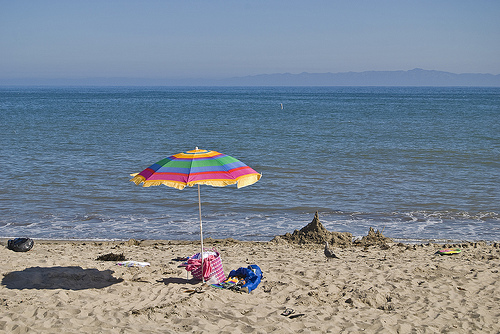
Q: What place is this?
A: It is a beach.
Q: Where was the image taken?
A: It was taken at the beach.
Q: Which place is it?
A: It is a beach.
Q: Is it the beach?
A: Yes, it is the beach.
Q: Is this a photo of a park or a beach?
A: It is showing a beach.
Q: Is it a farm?
A: No, it is a beach.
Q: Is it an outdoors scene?
A: Yes, it is outdoors.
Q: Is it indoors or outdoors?
A: It is outdoors.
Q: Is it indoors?
A: No, it is outdoors.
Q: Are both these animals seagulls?
A: Yes, all the animals are seagulls.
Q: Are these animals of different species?
A: No, all the animals are seagulls.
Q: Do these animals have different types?
A: No, all the animals are seagulls.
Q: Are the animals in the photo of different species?
A: No, all the animals are seagulls.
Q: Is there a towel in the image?
A: Yes, there is a towel.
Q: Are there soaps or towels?
A: Yes, there is a towel.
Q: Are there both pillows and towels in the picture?
A: No, there is a towel but no pillows.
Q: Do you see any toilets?
A: No, there are no toilets.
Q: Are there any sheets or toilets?
A: No, there are no toilets or sheets.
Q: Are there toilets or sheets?
A: No, there are no toilets or sheets.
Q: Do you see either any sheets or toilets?
A: No, there are no toilets or sheets.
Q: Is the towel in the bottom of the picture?
A: Yes, the towel is in the bottom of the image.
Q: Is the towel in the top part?
A: No, the towel is in the bottom of the image.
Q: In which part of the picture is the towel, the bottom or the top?
A: The towel is in the bottom of the image.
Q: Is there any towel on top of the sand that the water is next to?
A: Yes, there is a towel on top of the sand.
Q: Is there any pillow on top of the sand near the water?
A: No, there is a towel on top of the sand.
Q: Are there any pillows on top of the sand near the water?
A: No, there is a towel on top of the sand.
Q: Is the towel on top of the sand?
A: Yes, the towel is on top of the sand.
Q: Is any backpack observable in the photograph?
A: Yes, there is a backpack.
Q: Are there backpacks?
A: Yes, there is a backpack.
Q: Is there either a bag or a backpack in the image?
A: Yes, there is a backpack.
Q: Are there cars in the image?
A: No, there are no cars.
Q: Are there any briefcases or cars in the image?
A: No, there are no cars or briefcases.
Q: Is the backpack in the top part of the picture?
A: No, the backpack is in the bottom of the image.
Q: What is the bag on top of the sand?
A: The bag is a backpack.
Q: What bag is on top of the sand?
A: The bag is a backpack.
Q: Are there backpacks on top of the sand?
A: Yes, there is a backpack on top of the sand.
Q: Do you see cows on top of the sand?
A: No, there is a backpack on top of the sand.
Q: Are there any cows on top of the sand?
A: No, there is a backpack on top of the sand.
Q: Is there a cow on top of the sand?
A: No, there is a backpack on top of the sand.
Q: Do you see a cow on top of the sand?
A: No, there is a backpack on top of the sand.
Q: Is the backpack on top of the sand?
A: Yes, the backpack is on top of the sand.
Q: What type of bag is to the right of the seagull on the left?
A: The bag is a backpack.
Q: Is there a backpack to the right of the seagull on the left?
A: Yes, there is a backpack to the right of the seagull.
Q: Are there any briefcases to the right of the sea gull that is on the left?
A: No, there is a backpack to the right of the seagull.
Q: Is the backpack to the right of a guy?
A: No, the backpack is to the right of a seagull.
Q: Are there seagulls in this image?
A: Yes, there is a seagull.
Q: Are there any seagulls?
A: Yes, there is a seagull.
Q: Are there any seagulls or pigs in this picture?
A: Yes, there is a seagull.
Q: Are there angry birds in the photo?
A: No, there are no angry birds.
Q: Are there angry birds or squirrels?
A: No, there are no angry birds or squirrels.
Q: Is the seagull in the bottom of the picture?
A: Yes, the seagull is in the bottom of the image.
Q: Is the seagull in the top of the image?
A: No, the seagull is in the bottom of the image.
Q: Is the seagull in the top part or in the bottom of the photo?
A: The seagull is in the bottom of the image.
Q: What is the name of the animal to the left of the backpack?
A: The animal is a seagull.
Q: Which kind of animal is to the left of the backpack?
A: The animal is a seagull.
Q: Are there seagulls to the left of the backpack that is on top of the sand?
A: Yes, there is a seagull to the left of the backpack.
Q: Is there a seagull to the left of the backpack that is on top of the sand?
A: Yes, there is a seagull to the left of the backpack.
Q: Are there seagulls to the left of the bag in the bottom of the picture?
A: Yes, there is a seagull to the left of the backpack.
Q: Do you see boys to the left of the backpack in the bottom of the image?
A: No, there is a seagull to the left of the backpack.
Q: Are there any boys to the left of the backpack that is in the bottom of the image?
A: No, there is a seagull to the left of the backpack.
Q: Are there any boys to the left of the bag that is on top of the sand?
A: No, there is a seagull to the left of the backpack.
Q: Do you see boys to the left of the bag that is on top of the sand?
A: No, there is a seagull to the left of the backpack.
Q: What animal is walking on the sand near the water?
A: The sea gull is walking on the sand.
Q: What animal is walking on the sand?
A: The sea gull is walking on the sand.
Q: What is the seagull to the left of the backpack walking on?
A: The sea gull is walking on the sand.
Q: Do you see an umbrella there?
A: Yes, there is an umbrella.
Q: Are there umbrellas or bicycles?
A: Yes, there is an umbrella.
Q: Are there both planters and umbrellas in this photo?
A: No, there is an umbrella but no planters.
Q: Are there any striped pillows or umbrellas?
A: Yes, there is a striped umbrella.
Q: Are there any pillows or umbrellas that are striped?
A: Yes, the umbrella is striped.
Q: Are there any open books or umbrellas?
A: Yes, there is an open umbrella.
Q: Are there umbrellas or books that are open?
A: Yes, the umbrella is open.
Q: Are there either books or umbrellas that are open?
A: Yes, the umbrella is open.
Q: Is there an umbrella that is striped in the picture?
A: Yes, there is a striped umbrella.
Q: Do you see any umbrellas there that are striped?
A: Yes, there is an umbrella that is striped.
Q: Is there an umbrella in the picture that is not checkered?
A: Yes, there is a striped umbrella.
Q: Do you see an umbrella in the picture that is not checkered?
A: Yes, there is a striped umbrella.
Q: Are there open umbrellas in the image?
A: Yes, there is an open umbrella.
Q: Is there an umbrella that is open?
A: Yes, there is an umbrella that is open.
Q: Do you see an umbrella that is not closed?
A: Yes, there is a open umbrella.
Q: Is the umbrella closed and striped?
A: No, the umbrella is striped but open.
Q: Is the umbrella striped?
A: Yes, the umbrella is striped.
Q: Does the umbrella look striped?
A: Yes, the umbrella is striped.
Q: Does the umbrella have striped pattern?
A: Yes, the umbrella is striped.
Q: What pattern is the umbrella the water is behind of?
A: The umbrella is striped.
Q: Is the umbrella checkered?
A: No, the umbrella is striped.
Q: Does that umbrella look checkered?
A: No, the umbrella is striped.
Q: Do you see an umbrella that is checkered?
A: No, there is an umbrella but it is striped.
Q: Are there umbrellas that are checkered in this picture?
A: No, there is an umbrella but it is striped.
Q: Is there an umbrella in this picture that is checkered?
A: No, there is an umbrella but it is striped.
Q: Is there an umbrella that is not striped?
A: No, there is an umbrella but it is striped.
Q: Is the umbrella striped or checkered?
A: The umbrella is striped.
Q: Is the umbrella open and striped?
A: Yes, the umbrella is open and striped.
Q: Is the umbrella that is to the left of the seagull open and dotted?
A: No, the umbrella is open but striped.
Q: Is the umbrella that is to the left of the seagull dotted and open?
A: No, the umbrella is open but striped.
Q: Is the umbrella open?
A: Yes, the umbrella is open.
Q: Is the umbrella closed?
A: No, the umbrella is open.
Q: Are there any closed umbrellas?
A: No, there is an umbrella but it is open.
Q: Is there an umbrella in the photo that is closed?
A: No, there is an umbrella but it is open.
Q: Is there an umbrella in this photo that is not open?
A: No, there is an umbrella but it is open.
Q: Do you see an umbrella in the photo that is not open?
A: No, there is an umbrella but it is open.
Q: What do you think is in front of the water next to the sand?
A: The umbrella is in front of the water.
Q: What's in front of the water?
A: The umbrella is in front of the water.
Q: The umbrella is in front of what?
A: The umbrella is in front of the water.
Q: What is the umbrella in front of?
A: The umbrella is in front of the water.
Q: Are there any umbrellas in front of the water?
A: Yes, there is an umbrella in front of the water.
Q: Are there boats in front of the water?
A: No, there is an umbrella in front of the water.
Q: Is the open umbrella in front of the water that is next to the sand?
A: Yes, the umbrella is in front of the water.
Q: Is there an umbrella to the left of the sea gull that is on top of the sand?
A: Yes, there is an umbrella to the left of the sea gull.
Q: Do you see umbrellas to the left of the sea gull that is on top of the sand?
A: Yes, there is an umbrella to the left of the sea gull.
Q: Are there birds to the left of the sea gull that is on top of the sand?
A: No, there is an umbrella to the left of the seagull.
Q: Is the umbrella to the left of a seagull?
A: Yes, the umbrella is to the left of a seagull.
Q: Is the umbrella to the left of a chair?
A: No, the umbrella is to the left of a seagull.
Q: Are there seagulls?
A: Yes, there is a seagull.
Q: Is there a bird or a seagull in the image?
A: Yes, there is a seagull.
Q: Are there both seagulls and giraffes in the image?
A: No, there is a seagull but no giraffes.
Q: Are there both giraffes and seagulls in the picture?
A: No, there is a seagull but no giraffes.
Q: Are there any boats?
A: No, there are no boats.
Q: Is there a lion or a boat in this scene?
A: No, there are no boats or lions.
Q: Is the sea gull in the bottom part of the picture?
A: Yes, the sea gull is in the bottom of the image.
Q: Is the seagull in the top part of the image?
A: No, the seagull is in the bottom of the image.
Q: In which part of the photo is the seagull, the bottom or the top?
A: The seagull is in the bottom of the image.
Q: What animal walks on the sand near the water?
A: The sea gull walks on the sand.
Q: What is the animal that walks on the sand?
A: The animal is a seagull.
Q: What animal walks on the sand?
A: The animal is a seagull.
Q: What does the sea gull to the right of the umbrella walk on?
A: The seagull walks on the sand.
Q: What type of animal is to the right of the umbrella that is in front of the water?
A: The animal is a seagull.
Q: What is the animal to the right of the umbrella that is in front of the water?
A: The animal is a seagull.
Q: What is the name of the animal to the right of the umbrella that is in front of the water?
A: The animal is a seagull.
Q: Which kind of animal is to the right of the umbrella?
A: The animal is a seagull.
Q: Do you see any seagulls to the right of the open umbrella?
A: Yes, there is a seagull to the right of the umbrella.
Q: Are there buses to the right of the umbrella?
A: No, there is a seagull to the right of the umbrella.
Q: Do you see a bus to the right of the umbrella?
A: No, there is a seagull to the right of the umbrella.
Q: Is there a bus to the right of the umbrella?
A: No, there is a seagull to the right of the umbrella.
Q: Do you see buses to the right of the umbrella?
A: No, there is a seagull to the right of the umbrella.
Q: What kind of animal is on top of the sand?
A: The animal is a seagull.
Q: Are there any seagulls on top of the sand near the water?
A: Yes, there is a seagull on top of the sand.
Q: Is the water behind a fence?
A: No, the water is behind the umbrella.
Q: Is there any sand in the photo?
A: Yes, there is sand.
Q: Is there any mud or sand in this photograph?
A: Yes, there is sand.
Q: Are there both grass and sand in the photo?
A: No, there is sand but no grass.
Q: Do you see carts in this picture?
A: No, there are no carts.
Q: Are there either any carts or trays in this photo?
A: No, there are no carts or trays.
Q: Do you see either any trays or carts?
A: No, there are no carts or trays.